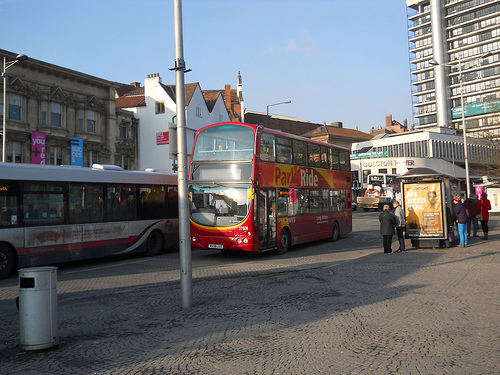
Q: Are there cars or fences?
A: No, there are no cars or fences.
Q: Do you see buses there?
A: Yes, there is a bus.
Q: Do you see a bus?
A: Yes, there is a bus.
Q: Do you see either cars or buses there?
A: Yes, there is a bus.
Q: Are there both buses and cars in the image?
A: No, there is a bus but no cars.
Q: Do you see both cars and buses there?
A: No, there is a bus but no cars.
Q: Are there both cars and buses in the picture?
A: No, there is a bus but no cars.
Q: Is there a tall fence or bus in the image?
A: Yes, there is a tall bus.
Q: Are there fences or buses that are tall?
A: Yes, the bus is tall.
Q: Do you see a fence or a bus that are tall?
A: Yes, the bus is tall.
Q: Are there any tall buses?
A: Yes, there is a tall bus.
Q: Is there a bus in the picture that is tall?
A: Yes, there is a tall bus.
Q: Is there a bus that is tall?
A: Yes, there is a bus that is tall.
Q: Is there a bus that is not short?
A: Yes, there is a tall bus.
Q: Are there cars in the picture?
A: No, there are no cars.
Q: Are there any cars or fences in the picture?
A: No, there are no cars or fences.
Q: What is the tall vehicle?
A: The vehicle is a bus.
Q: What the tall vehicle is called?
A: The vehicle is a bus.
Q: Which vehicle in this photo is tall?
A: The vehicle is a bus.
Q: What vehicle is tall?
A: The vehicle is a bus.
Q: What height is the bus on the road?
A: The bus is tall.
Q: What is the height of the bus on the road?
A: The bus is tall.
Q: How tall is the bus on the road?
A: The bus is tall.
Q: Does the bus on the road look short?
A: No, the bus is tall.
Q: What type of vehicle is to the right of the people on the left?
A: The vehicle is a bus.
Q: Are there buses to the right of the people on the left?
A: Yes, there is a bus to the right of the people.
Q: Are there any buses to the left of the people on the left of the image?
A: No, the bus is to the right of the people.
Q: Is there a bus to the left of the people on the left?
A: No, the bus is to the right of the people.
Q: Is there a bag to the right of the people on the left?
A: No, there is a bus to the right of the people.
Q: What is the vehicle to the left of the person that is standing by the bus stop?
A: The vehicle is a bus.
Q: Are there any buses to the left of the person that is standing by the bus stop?
A: Yes, there is a bus to the left of the person.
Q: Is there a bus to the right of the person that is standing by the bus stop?
A: No, the bus is to the left of the person.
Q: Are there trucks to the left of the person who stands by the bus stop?
A: No, there is a bus to the left of the person.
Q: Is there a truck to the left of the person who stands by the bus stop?
A: No, there is a bus to the left of the person.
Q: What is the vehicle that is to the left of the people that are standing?
A: The vehicle is a bus.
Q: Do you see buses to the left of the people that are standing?
A: Yes, there is a bus to the left of the people.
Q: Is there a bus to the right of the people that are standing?
A: No, the bus is to the left of the people.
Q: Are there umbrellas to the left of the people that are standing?
A: No, there is a bus to the left of the people.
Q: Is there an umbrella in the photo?
A: No, there are no umbrellas.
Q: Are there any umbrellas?
A: No, there are no umbrellas.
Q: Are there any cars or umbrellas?
A: No, there are no umbrellas or cars.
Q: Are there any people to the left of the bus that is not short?
A: Yes, there are people to the left of the bus.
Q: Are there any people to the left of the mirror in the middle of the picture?
A: Yes, there are people to the left of the mirror.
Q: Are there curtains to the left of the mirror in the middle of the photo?
A: No, there are people to the left of the mirror.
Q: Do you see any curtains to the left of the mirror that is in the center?
A: No, there are people to the left of the mirror.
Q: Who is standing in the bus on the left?
A: The people are standing in the bus.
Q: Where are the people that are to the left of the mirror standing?
A: The people are standing in the bus.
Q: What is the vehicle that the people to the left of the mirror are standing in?
A: The vehicle is a bus.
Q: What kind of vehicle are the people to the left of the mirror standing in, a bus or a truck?
A: The people are standing in a bus.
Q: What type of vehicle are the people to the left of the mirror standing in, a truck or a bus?
A: The people are standing in a bus.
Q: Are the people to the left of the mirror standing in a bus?
A: Yes, the people are standing in a bus.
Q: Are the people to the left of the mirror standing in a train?
A: No, the people are standing in a bus.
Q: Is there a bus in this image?
A: Yes, there is a bus.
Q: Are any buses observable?
A: Yes, there is a bus.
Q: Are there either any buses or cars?
A: Yes, there is a bus.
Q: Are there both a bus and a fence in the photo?
A: No, there is a bus but no fences.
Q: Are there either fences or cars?
A: No, there are no cars or fences.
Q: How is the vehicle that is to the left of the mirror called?
A: The vehicle is a bus.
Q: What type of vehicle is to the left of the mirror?
A: The vehicle is a bus.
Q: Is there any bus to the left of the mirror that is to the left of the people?
A: Yes, there is a bus to the left of the mirror.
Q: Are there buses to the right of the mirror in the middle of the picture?
A: No, the bus is to the left of the mirror.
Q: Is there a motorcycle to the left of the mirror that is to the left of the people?
A: No, there is a bus to the left of the mirror.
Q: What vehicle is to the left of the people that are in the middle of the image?
A: The vehicle is a bus.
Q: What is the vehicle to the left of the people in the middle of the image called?
A: The vehicle is a bus.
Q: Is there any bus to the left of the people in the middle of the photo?
A: Yes, there is a bus to the left of the people.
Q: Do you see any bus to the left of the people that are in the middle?
A: Yes, there is a bus to the left of the people.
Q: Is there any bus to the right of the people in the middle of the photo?
A: No, the bus is to the left of the people.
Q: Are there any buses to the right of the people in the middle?
A: No, the bus is to the left of the people.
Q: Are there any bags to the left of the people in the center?
A: No, there is a bus to the left of the people.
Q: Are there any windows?
A: Yes, there is a window.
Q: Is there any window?
A: Yes, there is a window.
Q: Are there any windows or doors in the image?
A: Yes, there is a window.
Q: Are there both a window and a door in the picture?
A: Yes, there are both a window and a door.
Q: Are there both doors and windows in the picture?
A: Yes, there are both a window and a door.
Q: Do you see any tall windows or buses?
A: Yes, there is a tall window.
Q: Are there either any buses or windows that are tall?
A: Yes, the window is tall.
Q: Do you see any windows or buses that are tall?
A: Yes, the window is tall.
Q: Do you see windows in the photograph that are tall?
A: Yes, there is a tall window.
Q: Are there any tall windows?
A: Yes, there is a tall window.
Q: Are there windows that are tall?
A: Yes, there is a window that is tall.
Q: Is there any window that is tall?
A: Yes, there is a window that is tall.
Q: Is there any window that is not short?
A: Yes, there is a tall window.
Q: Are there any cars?
A: No, there are no cars.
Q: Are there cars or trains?
A: No, there are no cars or trains.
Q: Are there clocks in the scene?
A: No, there are no clocks.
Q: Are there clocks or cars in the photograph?
A: No, there are no clocks or cars.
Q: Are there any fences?
A: No, there are no fences.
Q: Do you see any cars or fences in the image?
A: No, there are no fences or cars.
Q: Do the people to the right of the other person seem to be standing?
A: Yes, the people are standing.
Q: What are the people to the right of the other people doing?
A: The people are standing.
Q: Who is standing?
A: The people are standing.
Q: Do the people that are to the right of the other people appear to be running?
A: No, the people are standing.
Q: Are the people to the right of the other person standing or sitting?
A: The people are standing.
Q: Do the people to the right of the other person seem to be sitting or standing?
A: The people are standing.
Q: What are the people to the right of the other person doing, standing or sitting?
A: The people are standing.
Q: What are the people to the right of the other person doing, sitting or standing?
A: The people are standing.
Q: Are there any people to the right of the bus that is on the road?
A: Yes, there are people to the right of the bus.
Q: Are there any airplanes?
A: No, there are no airplanes.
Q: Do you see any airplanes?
A: No, there are no airplanes.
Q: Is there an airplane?
A: No, there are no airplanes.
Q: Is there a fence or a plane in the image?
A: No, there are no airplanes or fences.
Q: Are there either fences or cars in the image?
A: No, there are no cars or fences.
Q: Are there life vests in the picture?
A: No, there are no life vests.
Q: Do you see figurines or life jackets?
A: No, there are no life jackets or figurines.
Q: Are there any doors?
A: Yes, there is a door.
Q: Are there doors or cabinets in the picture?
A: Yes, there is a door.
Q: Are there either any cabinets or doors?
A: Yes, there is a door.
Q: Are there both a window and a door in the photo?
A: Yes, there are both a door and a window.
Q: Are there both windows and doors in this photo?
A: Yes, there are both a door and a window.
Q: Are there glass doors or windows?
A: Yes, there is a glass door.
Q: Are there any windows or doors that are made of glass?
A: Yes, the door is made of glass.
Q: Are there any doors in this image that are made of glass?
A: Yes, there is a door that is made of glass.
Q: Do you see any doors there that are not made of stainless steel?
A: Yes, there is a door that is made of glass.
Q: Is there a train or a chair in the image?
A: No, there are no chairs or trains.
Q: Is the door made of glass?
A: Yes, the door is made of glass.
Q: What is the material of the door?
A: The door is made of glass.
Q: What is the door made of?
A: The door is made of glass.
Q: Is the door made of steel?
A: No, the door is made of glass.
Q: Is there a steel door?
A: No, there is a door but it is made of glass.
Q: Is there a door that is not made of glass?
A: No, there is a door but it is made of glass.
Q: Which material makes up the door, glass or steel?
A: The door is made of glass.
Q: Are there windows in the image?
A: Yes, there is a window.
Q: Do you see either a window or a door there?
A: Yes, there is a window.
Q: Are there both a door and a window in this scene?
A: Yes, there are both a window and a door.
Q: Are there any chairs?
A: No, there are no chairs.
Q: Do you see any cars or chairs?
A: No, there are no chairs or cars.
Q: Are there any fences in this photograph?
A: No, there are no fences.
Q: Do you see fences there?
A: No, there are no fences.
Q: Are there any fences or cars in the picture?
A: No, there are no fences or cars.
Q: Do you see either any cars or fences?
A: No, there are no fences or cars.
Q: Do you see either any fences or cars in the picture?
A: No, there are no fences or cars.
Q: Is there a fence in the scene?
A: No, there are no fences.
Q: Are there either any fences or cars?
A: No, there are no fences or cars.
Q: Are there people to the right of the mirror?
A: Yes, there are people to the right of the mirror.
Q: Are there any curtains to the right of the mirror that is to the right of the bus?
A: No, there are people to the right of the mirror.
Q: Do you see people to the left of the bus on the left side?
A: No, the people are to the right of the bus.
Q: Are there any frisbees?
A: No, there are no frisbees.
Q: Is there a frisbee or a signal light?
A: No, there are no frisbees or traffic lights.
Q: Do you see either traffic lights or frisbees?
A: No, there are no frisbees or traffic lights.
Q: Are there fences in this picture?
A: No, there are no fences.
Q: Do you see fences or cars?
A: No, there are no fences or cars.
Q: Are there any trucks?
A: No, there are no trucks.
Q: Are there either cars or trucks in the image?
A: No, there are no trucks or cars.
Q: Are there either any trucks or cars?
A: No, there are no trucks or cars.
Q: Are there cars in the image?
A: No, there are no cars.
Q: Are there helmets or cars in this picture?
A: No, there are no cars or helmets.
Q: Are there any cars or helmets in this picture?
A: No, there are no cars or helmets.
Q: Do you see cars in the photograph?
A: No, there are no cars.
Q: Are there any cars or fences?
A: No, there are no cars or fences.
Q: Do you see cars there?
A: No, there are no cars.